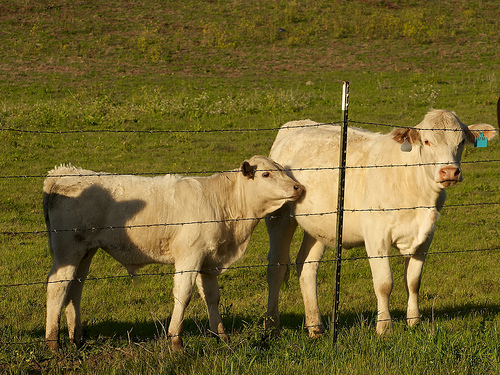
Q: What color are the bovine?
A: White.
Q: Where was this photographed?
A: Cattle ranch.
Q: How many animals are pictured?
A: Two.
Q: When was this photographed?
A: Daytime.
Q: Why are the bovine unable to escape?
A: The fence.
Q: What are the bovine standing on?
A: Grass.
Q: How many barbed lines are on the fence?
A: Five.